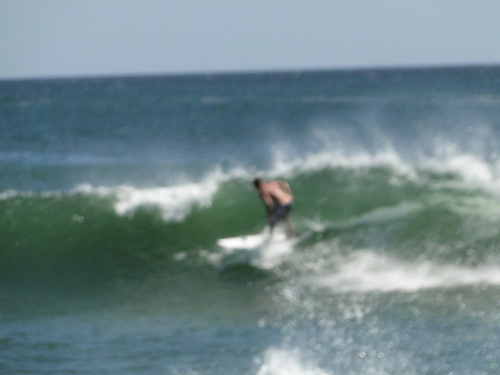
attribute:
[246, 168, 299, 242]
surfer — shirtless, balancing, riding, surfing, blurry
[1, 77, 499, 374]
water — wavy, white, foaming, splashing, curling, clear, reflecting, cresting, crashing, blue, still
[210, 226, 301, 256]
board — white, designed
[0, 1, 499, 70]
sky — blue, clear